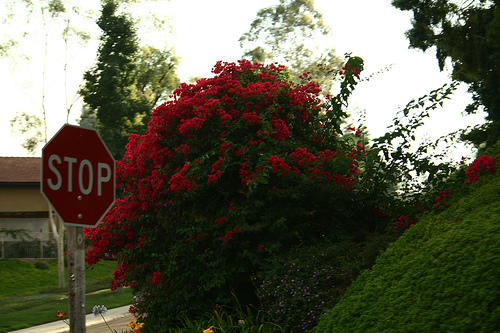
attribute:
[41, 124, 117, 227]
stop sign — red, white, octogonal, eight sided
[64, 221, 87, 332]
post — wooden, grimy, wood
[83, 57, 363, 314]
plant — flowering, purple, small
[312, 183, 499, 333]
hill — steep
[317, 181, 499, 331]
ground cover — green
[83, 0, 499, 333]
plants — green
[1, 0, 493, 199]
sky — clear, white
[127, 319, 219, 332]
flowers — yellow, little, red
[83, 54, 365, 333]
bush — big, red, large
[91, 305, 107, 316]
flower — blue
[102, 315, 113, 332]
stem — long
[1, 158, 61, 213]
roof — brown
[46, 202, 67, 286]
trunk — tall, thin, white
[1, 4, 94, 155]
branches — thin, long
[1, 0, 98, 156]
tree — tall, slender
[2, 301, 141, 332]
sidewalk — white, little, paved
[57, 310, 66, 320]
flower — red, yellow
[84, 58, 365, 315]
flowers — red, tiny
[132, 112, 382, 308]
leaves — green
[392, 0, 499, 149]
leaves — green